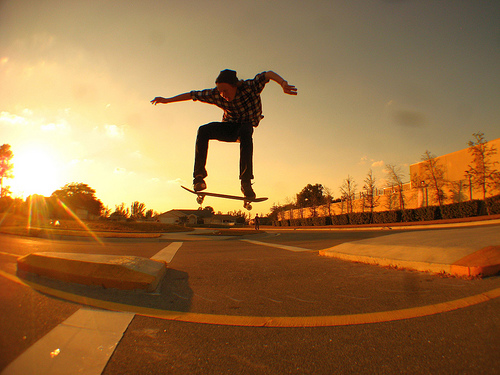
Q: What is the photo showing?
A: It is showing a skate park.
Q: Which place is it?
A: It is a skate park.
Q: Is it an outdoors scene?
A: Yes, it is outdoors.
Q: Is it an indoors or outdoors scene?
A: It is outdoors.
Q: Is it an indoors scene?
A: No, it is outdoors.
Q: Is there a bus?
A: No, there are no buses.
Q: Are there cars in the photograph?
A: No, there are no cars.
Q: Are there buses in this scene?
A: No, there are no buses.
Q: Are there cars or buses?
A: No, there are no buses or cars.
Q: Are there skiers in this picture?
A: No, there are no skiers.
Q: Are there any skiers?
A: No, there are no skiers.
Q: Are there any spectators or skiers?
A: No, there are no skiers or spectators.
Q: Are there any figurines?
A: No, there are no figurines.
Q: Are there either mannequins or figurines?
A: No, there are no figurines or mannequins.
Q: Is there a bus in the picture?
A: No, there are no buses.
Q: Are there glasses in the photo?
A: No, there are no glasses.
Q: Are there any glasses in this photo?
A: No, there are no glasses.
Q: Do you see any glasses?
A: No, there are no glasses.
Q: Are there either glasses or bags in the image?
A: No, there are no glasses or bags.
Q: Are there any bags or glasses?
A: No, there are no glasses or bags.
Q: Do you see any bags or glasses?
A: No, there are no glasses or bags.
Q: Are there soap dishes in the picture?
A: No, there are no soap dishes.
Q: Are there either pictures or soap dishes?
A: No, there are no soap dishes or pictures.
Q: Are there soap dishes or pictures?
A: No, there are no soap dishes or pictures.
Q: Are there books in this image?
A: No, there are no books.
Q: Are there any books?
A: No, there are no books.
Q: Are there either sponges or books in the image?
A: No, there are no books or sponges.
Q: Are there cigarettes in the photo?
A: No, there are no cigarettes.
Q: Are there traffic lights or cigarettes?
A: No, there are no cigarettes or traffic lights.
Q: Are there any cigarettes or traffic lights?
A: No, there are no cigarettes or traffic lights.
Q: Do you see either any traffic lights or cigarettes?
A: No, there are no cigarettes or traffic lights.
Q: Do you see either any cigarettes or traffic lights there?
A: No, there are no cigarettes or traffic lights.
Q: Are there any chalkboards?
A: No, there are no chalkboards.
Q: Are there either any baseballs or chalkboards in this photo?
A: No, there are no chalkboards or baseballs.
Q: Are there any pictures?
A: No, there are no pictures.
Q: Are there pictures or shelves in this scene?
A: No, there are no pictures or shelves.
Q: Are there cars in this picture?
A: No, there are no cars.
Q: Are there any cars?
A: No, there are no cars.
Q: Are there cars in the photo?
A: No, there are no cars.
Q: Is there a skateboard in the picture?
A: Yes, there is a skateboard.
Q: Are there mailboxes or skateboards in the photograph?
A: Yes, there is a skateboard.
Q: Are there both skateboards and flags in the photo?
A: No, there is a skateboard but no flags.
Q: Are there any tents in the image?
A: No, there are no tents.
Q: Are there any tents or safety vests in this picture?
A: No, there are no tents or safety vests.